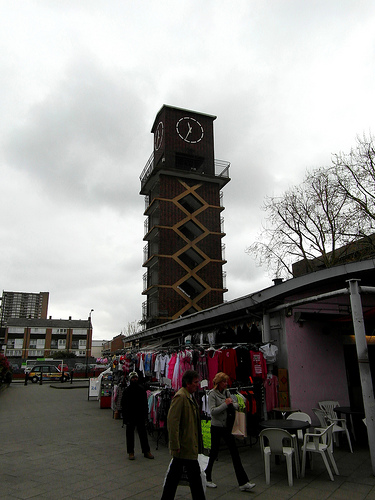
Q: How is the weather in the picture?
A: It is cloudy.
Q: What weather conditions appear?
A: It is cloudy.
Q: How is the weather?
A: It is cloudy.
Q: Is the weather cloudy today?
A: Yes, it is cloudy.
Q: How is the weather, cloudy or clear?
A: It is cloudy.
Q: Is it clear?
A: No, it is cloudy.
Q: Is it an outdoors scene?
A: Yes, it is outdoors.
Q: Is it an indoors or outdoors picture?
A: It is outdoors.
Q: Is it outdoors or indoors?
A: It is outdoors.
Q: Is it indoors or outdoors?
A: It is outdoors.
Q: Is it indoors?
A: No, it is outdoors.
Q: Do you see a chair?
A: Yes, there is a chair.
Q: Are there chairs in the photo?
A: Yes, there is a chair.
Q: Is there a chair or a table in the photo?
A: Yes, there is a chair.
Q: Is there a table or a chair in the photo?
A: Yes, there is a chair.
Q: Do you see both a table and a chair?
A: Yes, there are both a chair and a table.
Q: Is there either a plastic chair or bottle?
A: Yes, there is a plastic chair.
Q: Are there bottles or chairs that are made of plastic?
A: Yes, the chair is made of plastic.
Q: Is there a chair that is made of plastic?
A: Yes, there is a chair that is made of plastic.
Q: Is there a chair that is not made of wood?
A: Yes, there is a chair that is made of plastic.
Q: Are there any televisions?
A: No, there are no televisions.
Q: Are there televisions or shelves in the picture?
A: No, there are no televisions or shelves.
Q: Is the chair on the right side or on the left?
A: The chair is on the right of the image.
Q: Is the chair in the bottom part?
A: Yes, the chair is in the bottom of the image.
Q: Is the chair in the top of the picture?
A: No, the chair is in the bottom of the image.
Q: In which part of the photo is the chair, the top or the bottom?
A: The chair is in the bottom of the image.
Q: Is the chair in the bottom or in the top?
A: The chair is in the bottom of the image.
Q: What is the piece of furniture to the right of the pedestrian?
A: The piece of furniture is a chair.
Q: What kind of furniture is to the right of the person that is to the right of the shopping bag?
A: The piece of furniture is a chair.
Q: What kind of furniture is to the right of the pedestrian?
A: The piece of furniture is a chair.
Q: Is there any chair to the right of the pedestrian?
A: Yes, there is a chair to the right of the pedestrian.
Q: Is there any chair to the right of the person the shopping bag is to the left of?
A: Yes, there is a chair to the right of the pedestrian.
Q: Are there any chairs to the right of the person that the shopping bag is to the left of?
A: Yes, there is a chair to the right of the pedestrian.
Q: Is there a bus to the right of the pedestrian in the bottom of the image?
A: No, there is a chair to the right of the pedestrian.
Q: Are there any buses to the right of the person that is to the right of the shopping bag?
A: No, there is a chair to the right of the pedestrian.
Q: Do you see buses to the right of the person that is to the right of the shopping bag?
A: No, there is a chair to the right of the pedestrian.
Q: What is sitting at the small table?
A: The chair is sitting at the table.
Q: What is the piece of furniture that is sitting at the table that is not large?
A: The piece of furniture is a chair.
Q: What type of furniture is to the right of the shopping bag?
A: The piece of furniture is a chair.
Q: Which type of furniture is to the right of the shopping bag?
A: The piece of furniture is a chair.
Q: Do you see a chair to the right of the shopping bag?
A: Yes, there is a chair to the right of the shopping bag.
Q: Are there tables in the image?
A: Yes, there is a table.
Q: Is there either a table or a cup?
A: Yes, there is a table.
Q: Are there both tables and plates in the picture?
A: No, there is a table but no plates.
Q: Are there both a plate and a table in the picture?
A: No, there is a table but no plates.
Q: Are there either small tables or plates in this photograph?
A: Yes, there is a small table.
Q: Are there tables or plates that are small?
A: Yes, the table is small.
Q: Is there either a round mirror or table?
A: Yes, there is a round table.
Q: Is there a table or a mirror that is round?
A: Yes, the table is round.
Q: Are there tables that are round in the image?
A: Yes, there is a round table.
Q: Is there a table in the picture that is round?
A: Yes, there is a table that is round.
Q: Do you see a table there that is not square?
A: Yes, there is a round table.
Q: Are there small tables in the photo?
A: Yes, there is a small table.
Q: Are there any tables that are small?
A: Yes, there is a table that is small.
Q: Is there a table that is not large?
A: Yes, there is a small table.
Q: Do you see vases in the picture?
A: No, there are no vases.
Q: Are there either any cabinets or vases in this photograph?
A: No, there are no vases or cabinets.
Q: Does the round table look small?
A: Yes, the table is small.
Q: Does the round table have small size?
A: Yes, the table is small.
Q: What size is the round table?
A: The table is small.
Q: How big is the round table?
A: The table is small.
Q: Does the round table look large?
A: No, the table is small.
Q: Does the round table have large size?
A: No, the table is small.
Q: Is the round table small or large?
A: The table is small.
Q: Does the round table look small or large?
A: The table is small.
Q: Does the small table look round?
A: Yes, the table is round.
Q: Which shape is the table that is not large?
A: The table is round.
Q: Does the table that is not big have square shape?
A: No, the table is round.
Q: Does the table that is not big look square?
A: No, the table is round.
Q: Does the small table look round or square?
A: The table is round.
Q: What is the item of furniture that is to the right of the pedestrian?
A: The piece of furniture is a table.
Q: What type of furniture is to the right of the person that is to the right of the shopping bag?
A: The piece of furniture is a table.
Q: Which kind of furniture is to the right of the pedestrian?
A: The piece of furniture is a table.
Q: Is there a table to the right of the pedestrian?
A: Yes, there is a table to the right of the pedestrian.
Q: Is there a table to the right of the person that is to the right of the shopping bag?
A: Yes, there is a table to the right of the pedestrian.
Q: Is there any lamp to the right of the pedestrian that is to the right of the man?
A: No, there is a table to the right of the pedestrian.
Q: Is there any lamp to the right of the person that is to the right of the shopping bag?
A: No, there is a table to the right of the pedestrian.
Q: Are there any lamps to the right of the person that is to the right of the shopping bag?
A: No, there is a table to the right of the pedestrian.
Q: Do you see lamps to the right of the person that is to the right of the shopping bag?
A: No, there is a table to the right of the pedestrian.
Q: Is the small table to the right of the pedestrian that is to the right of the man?
A: Yes, the table is to the right of the pedestrian.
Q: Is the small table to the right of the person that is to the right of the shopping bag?
A: Yes, the table is to the right of the pedestrian.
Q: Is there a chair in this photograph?
A: Yes, there is a chair.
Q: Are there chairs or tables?
A: Yes, there is a chair.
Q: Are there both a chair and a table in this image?
A: Yes, there are both a chair and a table.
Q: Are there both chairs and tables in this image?
A: Yes, there are both a chair and a table.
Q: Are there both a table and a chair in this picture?
A: Yes, there are both a chair and a table.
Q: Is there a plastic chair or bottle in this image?
A: Yes, there is a plastic chair.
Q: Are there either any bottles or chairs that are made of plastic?
A: Yes, the chair is made of plastic.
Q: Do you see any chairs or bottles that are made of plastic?
A: Yes, the chair is made of plastic.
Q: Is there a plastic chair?
A: Yes, there is a chair that is made of plastic.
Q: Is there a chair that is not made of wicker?
A: Yes, there is a chair that is made of plastic.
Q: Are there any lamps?
A: No, there are no lamps.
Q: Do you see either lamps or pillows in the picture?
A: No, there are no lamps or pillows.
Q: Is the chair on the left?
A: No, the chair is on the right of the image.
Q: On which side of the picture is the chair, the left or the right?
A: The chair is on the right of the image.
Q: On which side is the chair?
A: The chair is on the right of the image.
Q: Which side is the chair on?
A: The chair is on the right of the image.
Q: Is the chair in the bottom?
A: Yes, the chair is in the bottom of the image.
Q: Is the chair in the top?
A: No, the chair is in the bottom of the image.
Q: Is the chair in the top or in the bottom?
A: The chair is in the bottom of the image.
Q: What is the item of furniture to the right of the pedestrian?
A: The piece of furniture is a chair.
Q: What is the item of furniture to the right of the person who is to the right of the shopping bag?
A: The piece of furniture is a chair.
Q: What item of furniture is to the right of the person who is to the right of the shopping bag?
A: The piece of furniture is a chair.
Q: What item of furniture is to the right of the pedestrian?
A: The piece of furniture is a chair.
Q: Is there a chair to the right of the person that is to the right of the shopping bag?
A: Yes, there is a chair to the right of the pedestrian.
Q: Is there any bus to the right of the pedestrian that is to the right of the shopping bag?
A: No, there is a chair to the right of the pedestrian.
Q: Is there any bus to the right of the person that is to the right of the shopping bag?
A: No, there is a chair to the right of the pedestrian.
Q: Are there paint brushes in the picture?
A: No, there are no paint brushes.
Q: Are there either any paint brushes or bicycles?
A: No, there are no paint brushes or bicycles.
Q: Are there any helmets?
A: No, there are no helmets.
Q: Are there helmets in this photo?
A: No, there are no helmets.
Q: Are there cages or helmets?
A: No, there are no helmets or cages.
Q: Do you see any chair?
A: Yes, there is a chair.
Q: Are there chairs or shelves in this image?
A: Yes, there is a chair.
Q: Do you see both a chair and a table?
A: Yes, there are both a chair and a table.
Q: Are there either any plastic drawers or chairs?
A: Yes, there is a plastic chair.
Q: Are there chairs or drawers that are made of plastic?
A: Yes, the chair is made of plastic.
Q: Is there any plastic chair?
A: Yes, there is a chair that is made of plastic.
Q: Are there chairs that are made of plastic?
A: Yes, there is a chair that is made of plastic.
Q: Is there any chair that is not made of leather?
A: Yes, there is a chair that is made of plastic.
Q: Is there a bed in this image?
A: No, there are no beds.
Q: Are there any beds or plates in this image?
A: No, there are no beds or plates.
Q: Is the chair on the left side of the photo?
A: No, the chair is on the right of the image.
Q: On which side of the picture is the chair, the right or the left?
A: The chair is on the right of the image.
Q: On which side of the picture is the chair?
A: The chair is on the right of the image.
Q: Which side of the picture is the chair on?
A: The chair is on the right of the image.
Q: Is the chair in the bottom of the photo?
A: Yes, the chair is in the bottom of the image.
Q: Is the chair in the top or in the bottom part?
A: The chair is in the bottom of the image.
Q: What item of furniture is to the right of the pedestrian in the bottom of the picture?
A: The piece of furniture is a chair.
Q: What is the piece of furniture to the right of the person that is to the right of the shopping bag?
A: The piece of furniture is a chair.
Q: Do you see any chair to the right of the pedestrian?
A: Yes, there is a chair to the right of the pedestrian.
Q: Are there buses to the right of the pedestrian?
A: No, there is a chair to the right of the pedestrian.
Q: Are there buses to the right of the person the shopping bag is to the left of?
A: No, there is a chair to the right of the pedestrian.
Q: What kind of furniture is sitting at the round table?
A: The piece of furniture is a chair.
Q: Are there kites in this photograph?
A: No, there are no kites.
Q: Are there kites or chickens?
A: No, there are no kites or chickens.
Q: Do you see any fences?
A: No, there are no fences.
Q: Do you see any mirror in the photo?
A: No, there are no mirrors.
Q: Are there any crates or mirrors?
A: No, there are no mirrors or crates.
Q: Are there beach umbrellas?
A: No, there are no beach umbrellas.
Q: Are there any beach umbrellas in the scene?
A: No, there are no beach umbrellas.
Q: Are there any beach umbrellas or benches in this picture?
A: No, there are no beach umbrellas or benches.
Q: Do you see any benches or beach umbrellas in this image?
A: No, there are no beach umbrellas or benches.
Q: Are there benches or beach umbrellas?
A: No, there are no beach umbrellas or benches.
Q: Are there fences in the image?
A: No, there are no fences.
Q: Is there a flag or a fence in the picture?
A: No, there are no fences or flags.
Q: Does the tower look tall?
A: Yes, the tower is tall.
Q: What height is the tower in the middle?
A: The tower is tall.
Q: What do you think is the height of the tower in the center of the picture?
A: The tower is tall.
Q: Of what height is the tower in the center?
A: The tower is tall.